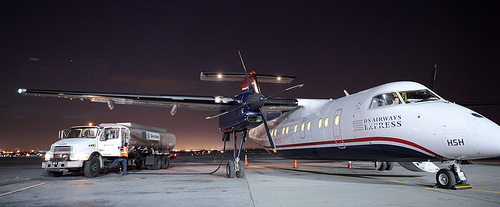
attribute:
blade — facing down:
[198, 57, 298, 108]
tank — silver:
[116, 116, 198, 157]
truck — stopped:
[40, 110, 177, 182]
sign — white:
[140, 128, 162, 139]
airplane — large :
[8, 39, 499, 189]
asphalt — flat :
[23, 180, 498, 205]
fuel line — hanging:
[208, 141, 228, 176]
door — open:
[98, 124, 123, 158]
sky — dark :
[361, 20, 413, 41]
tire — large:
[82, 152, 102, 177]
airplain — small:
[10, 31, 497, 186]